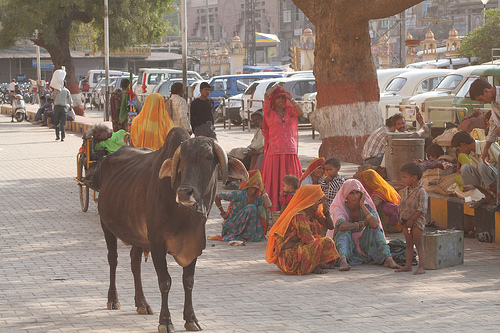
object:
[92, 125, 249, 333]
cow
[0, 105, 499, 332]
sidewalk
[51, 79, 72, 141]
man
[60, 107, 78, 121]
package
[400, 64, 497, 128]
cars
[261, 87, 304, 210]
woman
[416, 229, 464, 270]
suitcase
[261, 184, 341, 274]
outfit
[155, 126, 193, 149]
horns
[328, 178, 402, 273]
woman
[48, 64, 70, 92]
bag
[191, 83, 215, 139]
people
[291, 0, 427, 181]
tree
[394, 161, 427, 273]
boy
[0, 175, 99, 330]
shadow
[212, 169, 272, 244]
women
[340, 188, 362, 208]
saris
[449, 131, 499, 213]
men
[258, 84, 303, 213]
outfit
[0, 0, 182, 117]
tree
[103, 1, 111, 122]
poles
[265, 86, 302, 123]
shawl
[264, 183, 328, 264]
shawl